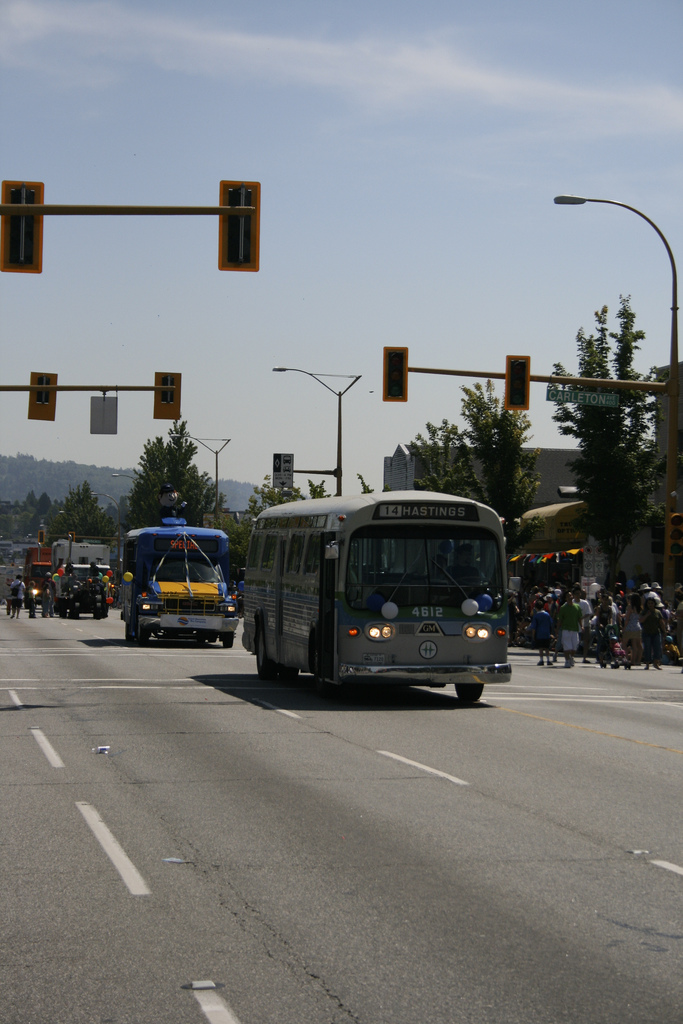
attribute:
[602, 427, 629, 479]
leaves — green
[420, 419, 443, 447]
leaves — green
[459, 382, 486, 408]
leaves — green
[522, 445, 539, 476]
leaves — green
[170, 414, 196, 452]
leaves — green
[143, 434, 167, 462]
leaves — green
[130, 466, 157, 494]
leaves — green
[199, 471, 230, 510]
leaves — green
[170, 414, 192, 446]
leaves — green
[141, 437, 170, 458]
leaves — green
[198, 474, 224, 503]
leaves — green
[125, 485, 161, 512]
leaves — green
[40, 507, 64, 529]
leaves — green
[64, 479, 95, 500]
leaves — green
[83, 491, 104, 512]
leaves — green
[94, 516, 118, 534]
leaves — green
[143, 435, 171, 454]
leaves — green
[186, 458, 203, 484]
leaves — green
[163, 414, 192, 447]
leaves — green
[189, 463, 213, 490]
leaves — green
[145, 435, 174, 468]
leaves — green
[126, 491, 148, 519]
leaves — green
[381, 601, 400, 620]
ballon — white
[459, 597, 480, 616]
ballon — white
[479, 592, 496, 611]
ballon — blue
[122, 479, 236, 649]
van — blue, yellow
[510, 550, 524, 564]
flag — colorful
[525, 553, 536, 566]
flag — colorful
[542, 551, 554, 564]
flag — colorful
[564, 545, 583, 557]
flag — colorful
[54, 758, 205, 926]
stripe — white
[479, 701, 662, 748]
line — yellow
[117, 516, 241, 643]
bus — blue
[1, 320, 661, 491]
cloud — white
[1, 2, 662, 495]
sky — blue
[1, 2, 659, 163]
cloud — white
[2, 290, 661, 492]
cloud — white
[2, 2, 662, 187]
cloud — white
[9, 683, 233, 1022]
lines — white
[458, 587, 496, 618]
balloons — blue, white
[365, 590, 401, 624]
balloons — blue, white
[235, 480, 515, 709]
bus — silver, white, large